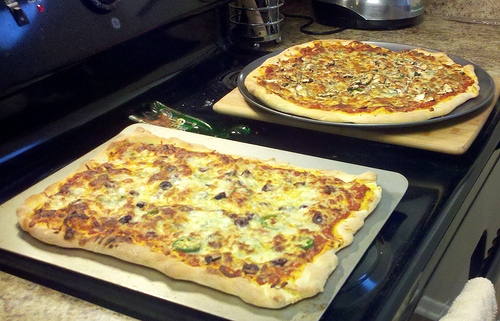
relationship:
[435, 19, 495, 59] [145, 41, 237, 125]
counter next to stove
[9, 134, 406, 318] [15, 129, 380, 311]
baking sheet with rectangle pizza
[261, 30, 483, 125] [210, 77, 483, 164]
pizza on board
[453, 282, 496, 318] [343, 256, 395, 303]
white towel on stove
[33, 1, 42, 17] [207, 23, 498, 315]
circle on stove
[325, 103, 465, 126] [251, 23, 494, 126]
crust on pizza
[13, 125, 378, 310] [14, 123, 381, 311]
rectangle crust on pizza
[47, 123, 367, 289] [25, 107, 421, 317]
pizza on sheet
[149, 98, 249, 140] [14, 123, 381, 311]
spoon between pizza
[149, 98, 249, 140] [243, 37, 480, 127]
spoon between pizza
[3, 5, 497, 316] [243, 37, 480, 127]
stove under pizza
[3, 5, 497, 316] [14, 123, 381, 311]
stove under pizza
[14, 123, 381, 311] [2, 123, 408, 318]
pizza on dish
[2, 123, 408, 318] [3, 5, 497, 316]
dish on stove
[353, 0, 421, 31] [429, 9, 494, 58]
kettle on counter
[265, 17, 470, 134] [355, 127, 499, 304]
pizza on stove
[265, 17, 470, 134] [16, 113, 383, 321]
pizza on trays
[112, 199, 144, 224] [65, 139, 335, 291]
olives on pizza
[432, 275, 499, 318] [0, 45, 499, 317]
towel on stove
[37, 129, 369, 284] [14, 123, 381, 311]
orange cheese on pizza